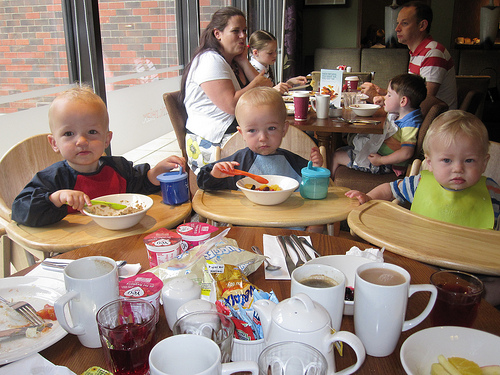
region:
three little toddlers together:
[8, 25, 498, 372]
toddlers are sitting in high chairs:
[4, 15, 499, 352]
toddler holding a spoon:
[177, 82, 353, 234]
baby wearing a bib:
[360, 93, 497, 254]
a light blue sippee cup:
[285, 132, 348, 241]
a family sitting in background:
[156, 0, 467, 190]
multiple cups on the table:
[48, 192, 459, 372]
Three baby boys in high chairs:
[16, 62, 498, 251]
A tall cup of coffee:
[350, 255, 433, 357]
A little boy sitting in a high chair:
[370, 101, 498, 261]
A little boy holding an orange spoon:
[209, 72, 310, 214]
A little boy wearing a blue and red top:
[18, 77, 163, 233]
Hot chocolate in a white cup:
[349, 250, 435, 362]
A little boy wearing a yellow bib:
[399, 104, 496, 246]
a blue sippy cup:
[301, 157, 329, 200]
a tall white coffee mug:
[352, 257, 438, 366]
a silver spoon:
[249, 241, 279, 277]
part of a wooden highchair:
[190, 121, 357, 232]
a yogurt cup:
[140, 230, 179, 265]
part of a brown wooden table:
[284, 105, 386, 135]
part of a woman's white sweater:
[185, 48, 241, 143]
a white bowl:
[350, 98, 380, 118]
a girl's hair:
[247, 29, 274, 54]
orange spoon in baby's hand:
[222, 158, 274, 188]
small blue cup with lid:
[297, 160, 335, 202]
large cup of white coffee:
[356, 257, 445, 362]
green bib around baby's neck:
[412, 168, 499, 244]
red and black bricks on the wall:
[113, 19, 164, 61]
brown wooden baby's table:
[352, 195, 494, 282]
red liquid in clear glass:
[88, 330, 155, 359]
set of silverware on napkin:
[274, 225, 324, 261]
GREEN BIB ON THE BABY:
[438, 193, 495, 220]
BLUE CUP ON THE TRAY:
[304, 163, 328, 196]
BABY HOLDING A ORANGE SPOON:
[236, 170, 268, 182]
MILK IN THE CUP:
[303, 185, 330, 195]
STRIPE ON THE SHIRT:
[398, 181, 412, 198]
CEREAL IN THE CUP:
[147, 233, 167, 262]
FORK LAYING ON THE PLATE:
[18, 292, 42, 332]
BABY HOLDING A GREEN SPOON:
[89, 202, 136, 208]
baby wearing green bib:
[408, 166, 495, 233]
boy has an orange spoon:
[225, 162, 267, 184]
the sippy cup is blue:
[156, 167, 188, 204]